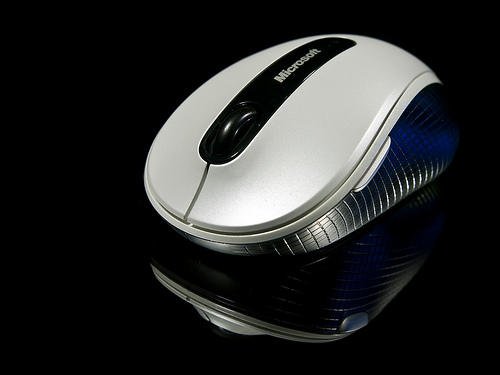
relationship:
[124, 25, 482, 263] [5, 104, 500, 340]
mouse on surface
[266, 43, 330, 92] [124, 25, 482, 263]
logo on mouse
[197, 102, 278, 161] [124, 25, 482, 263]
wheel on mouse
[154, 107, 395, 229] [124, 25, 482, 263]
buttons on mouse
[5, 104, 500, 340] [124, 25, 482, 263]
surface under mouse